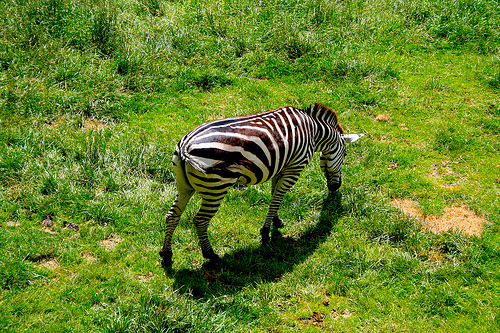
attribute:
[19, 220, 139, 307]
grass — dead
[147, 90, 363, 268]
zebra — stripe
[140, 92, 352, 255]
zebra — stripe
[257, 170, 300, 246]
leg — black, striped, white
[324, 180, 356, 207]
grass — green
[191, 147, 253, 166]
stripe —  zebra's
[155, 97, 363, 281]
zebra — stripe, eating, black, white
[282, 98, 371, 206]
zebra — eating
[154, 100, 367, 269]
zebra — stripe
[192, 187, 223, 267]
leg — black and white striped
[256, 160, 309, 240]
leg — black and white striped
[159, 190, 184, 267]
leg — black and white striped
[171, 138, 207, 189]
tail — black and white striped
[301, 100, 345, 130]
mane — black and white 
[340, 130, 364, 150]
ear —  white 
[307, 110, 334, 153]
neck — striped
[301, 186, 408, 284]
grass — green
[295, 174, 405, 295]
grass — green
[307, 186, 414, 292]
grass — green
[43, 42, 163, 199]
grass — green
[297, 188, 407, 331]
grass — green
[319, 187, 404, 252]
grass — green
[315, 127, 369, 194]
head — bent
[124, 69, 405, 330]
grass — green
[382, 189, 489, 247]
patch — dirt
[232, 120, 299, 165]
stripes — black, white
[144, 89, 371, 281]
zebra — grazing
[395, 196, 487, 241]
grass — dried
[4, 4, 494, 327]
field — large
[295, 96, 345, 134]
mane — black, white, brown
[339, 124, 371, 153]
ear — pointy